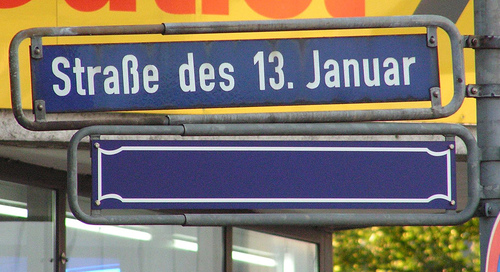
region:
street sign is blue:
[54, 118, 460, 235]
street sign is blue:
[10, 15, 488, 132]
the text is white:
[29, 40, 493, 150]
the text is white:
[29, 20, 152, 92]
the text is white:
[149, 32, 359, 149]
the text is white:
[275, 26, 492, 130]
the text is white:
[45, 33, 435, 108]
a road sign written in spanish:
[12, 22, 472, 236]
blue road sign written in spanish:
[15, 26, 440, 118]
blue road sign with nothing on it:
[67, 130, 498, 222]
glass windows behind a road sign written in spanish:
[12, 225, 205, 270]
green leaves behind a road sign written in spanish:
[359, 233, 460, 267]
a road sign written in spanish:
[20, 16, 467, 126]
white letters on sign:
[298, 38, 434, 109]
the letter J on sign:
[297, 45, 331, 95]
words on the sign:
[47, 33, 433, 115]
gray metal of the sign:
[364, 97, 421, 131]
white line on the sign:
[193, 140, 329, 165]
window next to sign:
[112, 230, 177, 262]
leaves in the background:
[371, 233, 441, 270]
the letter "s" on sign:
[210, 58, 241, 103]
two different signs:
[38, 7, 467, 257]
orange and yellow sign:
[56, 2, 377, 24]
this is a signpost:
[21, 48, 433, 92]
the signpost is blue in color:
[232, 166, 301, 197]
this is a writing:
[51, 53, 301, 106]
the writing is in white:
[266, 46, 408, 97]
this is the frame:
[59, 132, 77, 199]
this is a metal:
[65, 137, 81, 198]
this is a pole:
[463, 12, 499, 136]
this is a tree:
[335, 225, 382, 269]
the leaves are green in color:
[356, 229, 441, 266]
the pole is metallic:
[464, 7, 499, 42]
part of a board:
[268, 155, 313, 202]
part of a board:
[271, 170, 302, 202]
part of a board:
[268, 158, 294, 182]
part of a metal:
[286, 209, 312, 226]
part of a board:
[268, 162, 287, 176]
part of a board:
[294, 160, 311, 170]